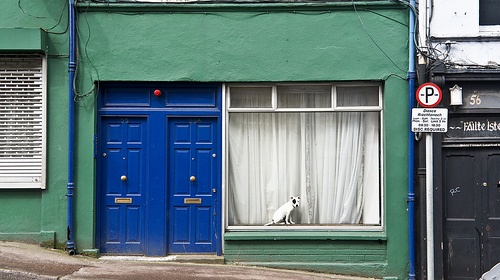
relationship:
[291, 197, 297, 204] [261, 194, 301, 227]
eye belonging to dog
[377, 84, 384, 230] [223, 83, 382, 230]
edge lining window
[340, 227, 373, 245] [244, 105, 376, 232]
edge of window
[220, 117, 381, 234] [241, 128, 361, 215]
window has curtains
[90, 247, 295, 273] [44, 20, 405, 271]
pavement in front of building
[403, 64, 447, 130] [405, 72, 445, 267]
sign on pole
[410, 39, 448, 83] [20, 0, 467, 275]
cords running in front of buildings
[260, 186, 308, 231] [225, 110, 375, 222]
dog on window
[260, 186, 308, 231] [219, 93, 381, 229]
dog on window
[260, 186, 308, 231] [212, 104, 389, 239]
dog on window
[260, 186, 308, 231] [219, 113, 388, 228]
dog on window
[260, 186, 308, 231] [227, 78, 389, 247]
dog on window